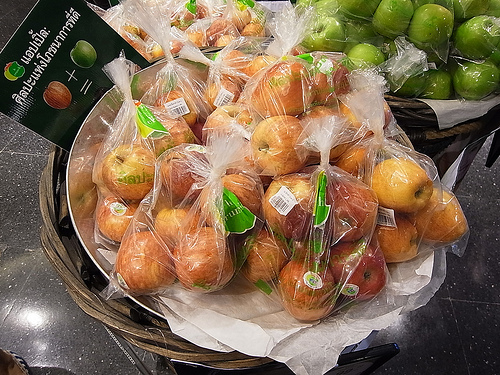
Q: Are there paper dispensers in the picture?
A: No, there are no paper dispensers.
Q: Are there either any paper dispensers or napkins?
A: No, there are no paper dispensers or napkins.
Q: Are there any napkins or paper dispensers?
A: No, there are no paper dispensers or napkins.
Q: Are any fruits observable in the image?
A: Yes, there is a fruit.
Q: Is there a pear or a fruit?
A: Yes, there is a fruit.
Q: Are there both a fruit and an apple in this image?
A: Yes, there are both a fruit and an apple.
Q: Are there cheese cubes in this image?
A: No, there are no cheese cubes.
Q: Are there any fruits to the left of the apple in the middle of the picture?
A: Yes, there is a fruit to the left of the apple.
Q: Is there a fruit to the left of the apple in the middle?
A: Yes, there is a fruit to the left of the apple.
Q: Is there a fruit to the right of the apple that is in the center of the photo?
A: No, the fruit is to the left of the apple.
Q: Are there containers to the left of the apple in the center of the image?
A: No, there is a fruit to the left of the apple.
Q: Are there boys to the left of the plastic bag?
A: No, there is a fruit to the left of the bag.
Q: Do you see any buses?
A: No, there are no buses.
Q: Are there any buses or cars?
A: No, there are no buses or cars.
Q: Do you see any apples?
A: Yes, there is an apple.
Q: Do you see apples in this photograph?
A: Yes, there is an apple.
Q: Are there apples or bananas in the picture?
A: Yes, there is an apple.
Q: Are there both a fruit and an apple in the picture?
A: Yes, there are both an apple and a fruit.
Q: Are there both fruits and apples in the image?
A: Yes, there are both an apple and a fruit.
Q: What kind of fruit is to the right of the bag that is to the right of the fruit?
A: The fruit is an apple.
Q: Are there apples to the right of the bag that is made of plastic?
A: Yes, there is an apple to the right of the bag.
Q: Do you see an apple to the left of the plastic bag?
A: No, the apple is to the right of the bag.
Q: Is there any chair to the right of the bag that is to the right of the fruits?
A: No, there is an apple to the right of the bag.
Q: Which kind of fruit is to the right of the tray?
A: The fruit is an apple.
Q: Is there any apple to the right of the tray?
A: Yes, there is an apple to the right of the tray.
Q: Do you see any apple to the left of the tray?
A: No, the apple is to the right of the tray.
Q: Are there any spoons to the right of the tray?
A: No, there is an apple to the right of the tray.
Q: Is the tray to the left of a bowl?
A: No, the tray is to the left of an apple.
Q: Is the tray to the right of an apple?
A: No, the tray is to the left of an apple.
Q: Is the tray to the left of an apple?
A: Yes, the tray is to the left of an apple.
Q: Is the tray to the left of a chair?
A: No, the tray is to the left of an apple.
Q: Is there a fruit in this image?
A: Yes, there is a fruit.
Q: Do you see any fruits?
A: Yes, there is a fruit.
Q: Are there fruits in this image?
A: Yes, there is a fruit.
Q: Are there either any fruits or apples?
A: Yes, there is a fruit.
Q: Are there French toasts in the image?
A: No, there are no French toasts.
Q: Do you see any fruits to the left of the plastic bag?
A: Yes, there is a fruit to the left of the bag.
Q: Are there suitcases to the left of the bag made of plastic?
A: No, there is a fruit to the left of the bag.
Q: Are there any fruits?
A: Yes, there is a fruit.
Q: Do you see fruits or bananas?
A: Yes, there is a fruit.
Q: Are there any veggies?
A: No, there are no veggies.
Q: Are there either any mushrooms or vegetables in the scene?
A: No, there are no vegetables or mushrooms.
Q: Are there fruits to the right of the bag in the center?
A: Yes, there is a fruit to the right of the bag.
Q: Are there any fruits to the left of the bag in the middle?
A: No, the fruit is to the right of the bag.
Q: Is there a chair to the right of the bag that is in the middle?
A: No, there is a fruit to the right of the bag.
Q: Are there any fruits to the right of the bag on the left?
A: Yes, there is a fruit to the right of the bag.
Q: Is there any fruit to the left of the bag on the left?
A: No, the fruit is to the right of the bag.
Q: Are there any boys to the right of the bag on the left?
A: No, there is a fruit to the right of the bag.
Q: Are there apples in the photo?
A: Yes, there are apples.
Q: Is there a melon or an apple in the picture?
A: Yes, there are apples.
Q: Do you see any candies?
A: No, there are no candies.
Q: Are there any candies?
A: No, there are no candies.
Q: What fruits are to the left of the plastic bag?
A: The fruits are apples.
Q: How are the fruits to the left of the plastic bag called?
A: The fruits are apples.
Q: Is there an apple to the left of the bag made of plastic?
A: Yes, there are apples to the left of the bag.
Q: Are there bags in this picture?
A: Yes, there is a bag.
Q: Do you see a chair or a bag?
A: Yes, there is a bag.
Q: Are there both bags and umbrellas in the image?
A: No, there is a bag but no umbrellas.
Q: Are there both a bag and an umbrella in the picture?
A: No, there is a bag but no umbrellas.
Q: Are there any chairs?
A: No, there are no chairs.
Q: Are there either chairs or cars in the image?
A: No, there are no chairs or cars.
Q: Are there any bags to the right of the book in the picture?
A: Yes, there is a bag to the right of the book.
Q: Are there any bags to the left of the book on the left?
A: No, the bag is to the right of the book.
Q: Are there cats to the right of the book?
A: No, there is a bag to the right of the book.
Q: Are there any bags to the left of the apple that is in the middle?
A: Yes, there is a bag to the left of the apple.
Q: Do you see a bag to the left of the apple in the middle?
A: Yes, there is a bag to the left of the apple.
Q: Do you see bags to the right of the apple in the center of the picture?
A: No, the bag is to the left of the apple.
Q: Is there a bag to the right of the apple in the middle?
A: No, the bag is to the left of the apple.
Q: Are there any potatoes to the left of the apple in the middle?
A: No, there is a bag to the left of the apple.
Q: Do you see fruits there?
A: Yes, there is a fruit.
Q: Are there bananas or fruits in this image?
A: Yes, there is a fruit.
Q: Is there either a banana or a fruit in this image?
A: Yes, there is a fruit.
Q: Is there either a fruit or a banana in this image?
A: Yes, there is a fruit.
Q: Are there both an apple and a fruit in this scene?
A: Yes, there are both a fruit and an apple.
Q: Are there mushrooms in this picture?
A: No, there are no mushrooms.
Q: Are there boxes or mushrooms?
A: No, there are no mushrooms or boxes.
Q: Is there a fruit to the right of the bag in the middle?
A: Yes, there is a fruit to the right of the bag.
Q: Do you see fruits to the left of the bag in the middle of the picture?
A: No, the fruit is to the right of the bag.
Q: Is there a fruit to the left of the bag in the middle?
A: No, the fruit is to the right of the bag.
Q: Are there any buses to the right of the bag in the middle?
A: No, there is a fruit to the right of the bag.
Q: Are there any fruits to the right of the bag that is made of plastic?
A: Yes, there is a fruit to the right of the bag.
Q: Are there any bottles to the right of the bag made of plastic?
A: No, there is a fruit to the right of the bag.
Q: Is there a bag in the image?
A: Yes, there is a bag.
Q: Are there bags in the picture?
A: Yes, there is a bag.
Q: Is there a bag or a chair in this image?
A: Yes, there is a bag.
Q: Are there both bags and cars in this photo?
A: No, there is a bag but no cars.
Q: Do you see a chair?
A: No, there are no chairs.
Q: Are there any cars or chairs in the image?
A: No, there are no chairs or cars.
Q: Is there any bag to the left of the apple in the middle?
A: Yes, there is a bag to the left of the apple.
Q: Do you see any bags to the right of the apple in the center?
A: No, the bag is to the left of the apple.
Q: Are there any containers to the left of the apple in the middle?
A: No, there is a bag to the left of the apple.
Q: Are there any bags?
A: Yes, there is a bag.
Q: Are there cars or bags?
A: Yes, there is a bag.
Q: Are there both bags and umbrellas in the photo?
A: No, there is a bag but no umbrellas.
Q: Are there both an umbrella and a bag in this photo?
A: No, there is a bag but no umbrellas.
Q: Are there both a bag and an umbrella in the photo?
A: No, there is a bag but no umbrellas.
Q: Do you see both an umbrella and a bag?
A: No, there is a bag but no umbrellas.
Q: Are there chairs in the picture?
A: No, there are no chairs.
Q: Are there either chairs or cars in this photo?
A: No, there are no chairs or cars.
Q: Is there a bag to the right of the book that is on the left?
A: Yes, there is a bag to the right of the book.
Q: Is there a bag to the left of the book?
A: No, the bag is to the right of the book.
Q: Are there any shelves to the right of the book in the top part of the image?
A: No, there is a bag to the right of the book.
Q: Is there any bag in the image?
A: Yes, there is a bag.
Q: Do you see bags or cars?
A: Yes, there is a bag.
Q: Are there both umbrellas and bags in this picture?
A: No, there is a bag but no umbrellas.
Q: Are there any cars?
A: No, there are no cars.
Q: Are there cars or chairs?
A: No, there are no cars or chairs.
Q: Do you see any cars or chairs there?
A: No, there are no cars or chairs.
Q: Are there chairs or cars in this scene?
A: No, there are no cars or chairs.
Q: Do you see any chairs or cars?
A: No, there are no cars or chairs.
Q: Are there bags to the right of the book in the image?
A: Yes, there is a bag to the right of the book.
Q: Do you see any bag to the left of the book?
A: No, the bag is to the right of the book.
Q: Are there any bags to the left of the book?
A: No, the bag is to the right of the book.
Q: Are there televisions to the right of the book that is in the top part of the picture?
A: No, there is a bag to the right of the book.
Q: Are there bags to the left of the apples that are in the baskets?
A: Yes, there is a bag to the left of the apples.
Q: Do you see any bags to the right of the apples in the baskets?
A: No, the bag is to the left of the apples.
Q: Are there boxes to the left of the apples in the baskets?
A: No, there is a bag to the left of the apples.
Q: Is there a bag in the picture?
A: Yes, there is a bag.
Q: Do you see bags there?
A: Yes, there is a bag.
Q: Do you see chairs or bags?
A: Yes, there is a bag.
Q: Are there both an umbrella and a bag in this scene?
A: No, there is a bag but no umbrellas.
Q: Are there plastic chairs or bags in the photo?
A: Yes, there is a plastic bag.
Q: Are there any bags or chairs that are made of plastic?
A: Yes, the bag is made of plastic.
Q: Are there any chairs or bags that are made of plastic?
A: Yes, the bag is made of plastic.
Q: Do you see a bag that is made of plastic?
A: Yes, there is a bag that is made of plastic.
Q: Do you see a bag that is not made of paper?
A: Yes, there is a bag that is made of plastic.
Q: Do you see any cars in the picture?
A: No, there are no cars.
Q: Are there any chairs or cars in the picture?
A: No, there are no cars or chairs.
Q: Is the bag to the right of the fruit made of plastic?
A: Yes, the bag is made of plastic.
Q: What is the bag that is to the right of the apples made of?
A: The bag is made of plastic.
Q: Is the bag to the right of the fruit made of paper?
A: No, the bag is made of plastic.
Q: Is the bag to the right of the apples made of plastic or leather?
A: The bag is made of plastic.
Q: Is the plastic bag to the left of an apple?
A: Yes, the bag is to the left of an apple.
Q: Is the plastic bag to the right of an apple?
A: No, the bag is to the left of an apple.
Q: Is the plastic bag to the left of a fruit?
A: No, the bag is to the right of a fruit.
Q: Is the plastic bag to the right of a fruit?
A: Yes, the bag is to the right of a fruit.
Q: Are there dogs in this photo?
A: No, there are no dogs.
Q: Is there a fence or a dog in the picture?
A: No, there are no dogs or fences.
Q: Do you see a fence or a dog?
A: No, there are no dogs or fences.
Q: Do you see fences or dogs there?
A: No, there are no dogs or fences.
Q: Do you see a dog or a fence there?
A: No, there are no dogs or fences.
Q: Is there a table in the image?
A: Yes, there is a table.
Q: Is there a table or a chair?
A: Yes, there is a table.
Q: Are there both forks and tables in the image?
A: No, there is a table but no forks.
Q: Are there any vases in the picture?
A: No, there are no vases.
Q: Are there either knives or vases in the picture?
A: No, there are no vases or knives.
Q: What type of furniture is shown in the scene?
A: The furniture is a table.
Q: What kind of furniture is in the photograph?
A: The furniture is a table.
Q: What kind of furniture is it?
A: The piece of furniture is a table.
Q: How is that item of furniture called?
A: This is a table.